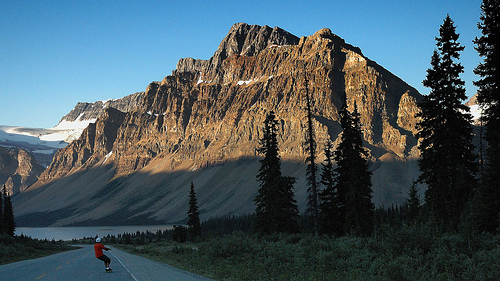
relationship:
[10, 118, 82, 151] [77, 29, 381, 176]
snow in the mountains